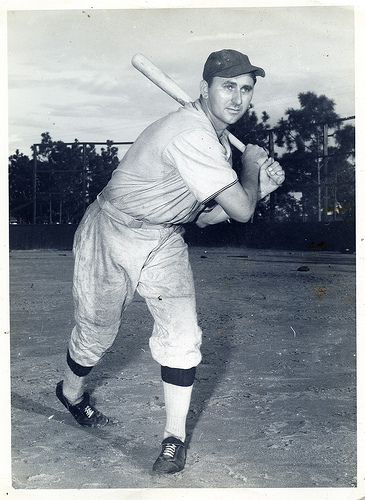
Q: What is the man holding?
A: A baseball bat.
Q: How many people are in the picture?
A: One.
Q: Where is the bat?
A: In the man's hands.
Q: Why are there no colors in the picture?
A: It's shot with black and white film.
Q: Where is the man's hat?
A: On his head.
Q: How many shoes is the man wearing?
A: Two.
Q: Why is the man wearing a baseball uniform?
A: He is a baseball player.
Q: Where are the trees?
A: Behind the fence.